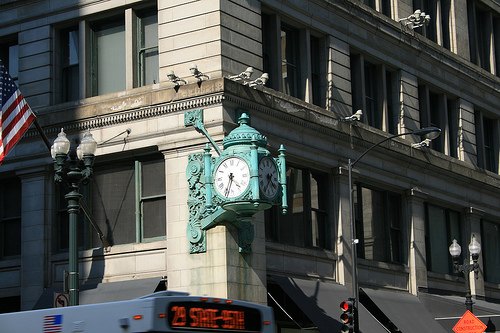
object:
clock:
[183, 108, 288, 253]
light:
[339, 299, 357, 325]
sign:
[451, 309, 486, 333]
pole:
[348, 157, 359, 290]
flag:
[0, 53, 59, 163]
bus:
[0, 290, 277, 332]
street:
[345, 316, 441, 333]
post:
[63, 184, 83, 307]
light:
[50, 127, 97, 160]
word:
[164, 300, 263, 330]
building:
[0, 0, 499, 333]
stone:
[171, 11, 205, 51]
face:
[213, 155, 251, 201]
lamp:
[50, 127, 97, 306]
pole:
[338, 253, 358, 333]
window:
[355, 174, 408, 264]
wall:
[222, 12, 437, 162]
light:
[449, 236, 481, 256]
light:
[467, 233, 484, 254]